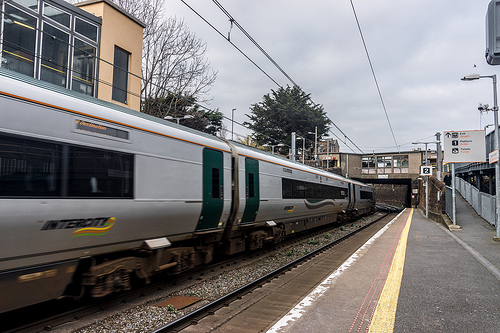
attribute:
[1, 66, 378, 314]
train — grey, pretty, long, commuter, passenger, parked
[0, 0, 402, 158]
wires — electrical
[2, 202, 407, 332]
rails — metal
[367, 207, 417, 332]
line — yellow, long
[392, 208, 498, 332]
platform — empty, cement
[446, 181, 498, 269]
ramp — for entrance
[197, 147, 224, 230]
door — green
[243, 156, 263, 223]
door — green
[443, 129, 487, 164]
sign — white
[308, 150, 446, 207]
bridge — covered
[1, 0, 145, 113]
building — tan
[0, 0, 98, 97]
windows — gray, white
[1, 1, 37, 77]
window — large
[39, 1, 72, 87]
window — large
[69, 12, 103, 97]
window — large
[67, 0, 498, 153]
sky — cloudy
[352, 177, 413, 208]
tunnel — small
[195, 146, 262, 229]
doors — green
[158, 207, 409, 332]
track — empty, old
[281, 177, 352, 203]
window — long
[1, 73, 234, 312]
car — silver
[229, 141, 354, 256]
car — silver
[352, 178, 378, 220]
car — silver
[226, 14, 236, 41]
wire — hanging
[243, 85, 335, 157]
tree — big, bushy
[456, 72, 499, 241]
pole — tall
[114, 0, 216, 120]
tree — tall, bare